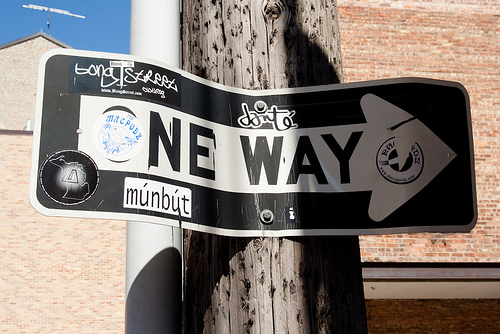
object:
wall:
[369, 9, 490, 147]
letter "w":
[238, 135, 282, 186]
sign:
[32, 50, 481, 234]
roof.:
[0, 28, 97, 63]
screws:
[253, 100, 268, 113]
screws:
[259, 210, 273, 224]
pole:
[123, 0, 181, 331]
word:
[239, 132, 363, 183]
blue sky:
[0, 1, 132, 53]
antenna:
[19, 4, 87, 20]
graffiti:
[74, 58, 179, 99]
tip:
[357, 92, 453, 222]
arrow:
[68, 87, 465, 226]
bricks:
[353, 15, 481, 62]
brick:
[450, 251, 465, 256]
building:
[333, 0, 497, 331]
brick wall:
[345, 0, 497, 79]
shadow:
[123, 245, 183, 330]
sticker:
[44, 145, 101, 205]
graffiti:
[238, 100, 299, 132]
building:
[0, 24, 124, 334]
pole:
[180, 0, 366, 334]